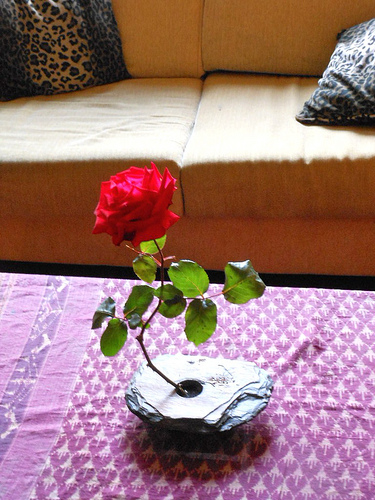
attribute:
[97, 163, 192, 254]
rose — red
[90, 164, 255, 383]
rose — red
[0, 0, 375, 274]
couch — orange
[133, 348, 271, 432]
vase — stone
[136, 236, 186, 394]
stem — curved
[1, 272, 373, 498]
cloth — purple 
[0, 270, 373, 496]
tablecloth — lavander, purple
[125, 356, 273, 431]
rock — grey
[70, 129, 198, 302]
rose — green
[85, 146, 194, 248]
rose — red, alive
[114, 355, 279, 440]
vase — rock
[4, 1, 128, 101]
pillow — leopard print, patterned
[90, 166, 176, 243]
rose — red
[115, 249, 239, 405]
stem — long , brown 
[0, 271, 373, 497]
cover — purple and white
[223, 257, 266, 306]
leaf — curled